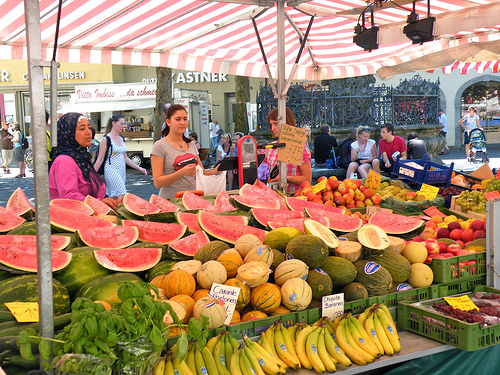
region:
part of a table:
[433, 345, 438, 353]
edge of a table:
[386, 337, 400, 354]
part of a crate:
[432, 305, 441, 320]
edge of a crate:
[426, 323, 431, 333]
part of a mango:
[323, 290, 330, 301]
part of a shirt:
[182, 180, 189, 190]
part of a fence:
[366, 104, 378, 124]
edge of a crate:
[420, 292, 431, 337]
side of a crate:
[435, 311, 442, 323]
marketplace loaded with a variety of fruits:
[1, 1, 498, 374]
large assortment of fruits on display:
[1, 159, 498, 374]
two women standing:
[46, 102, 228, 197]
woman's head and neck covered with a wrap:
[56, 113, 97, 154]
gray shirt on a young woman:
[149, 134, 202, 201]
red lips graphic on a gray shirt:
[170, 151, 201, 172]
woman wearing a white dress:
[95, 111, 147, 195]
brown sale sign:
[274, 123, 313, 166]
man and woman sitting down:
[343, 122, 410, 175]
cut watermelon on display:
[93, 244, 164, 275]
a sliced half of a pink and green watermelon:
[93, 245, 158, 271]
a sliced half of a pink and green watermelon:
[2, 244, 72, 271]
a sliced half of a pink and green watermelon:
[1, 230, 68, 252]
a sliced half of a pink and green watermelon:
[169, 230, 209, 255]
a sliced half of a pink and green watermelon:
[368, 209, 419, 237]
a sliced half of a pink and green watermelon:
[306, 205, 361, 234]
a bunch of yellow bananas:
[335, 310, 375, 362]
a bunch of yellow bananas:
[362, 303, 399, 353]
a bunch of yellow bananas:
[297, 321, 344, 371]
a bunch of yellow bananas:
[232, 340, 263, 373]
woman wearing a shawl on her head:
[46, 109, 107, 202]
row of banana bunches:
[141, 300, 403, 373]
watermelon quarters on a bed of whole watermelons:
[1, 177, 426, 316]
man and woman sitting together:
[345, 122, 407, 178]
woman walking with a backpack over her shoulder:
[91, 111, 148, 198]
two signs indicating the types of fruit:
[208, 279, 346, 326]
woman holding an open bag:
[148, 101, 226, 201]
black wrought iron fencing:
[254, 71, 444, 133]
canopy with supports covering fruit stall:
[1, 0, 498, 337]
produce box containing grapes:
[450, 177, 499, 222]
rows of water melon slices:
[2, 185, 430, 272]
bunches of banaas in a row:
[157, 301, 399, 373]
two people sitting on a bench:
[337, 119, 418, 179]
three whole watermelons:
[7, 242, 142, 322]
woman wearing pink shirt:
[43, 112, 108, 206]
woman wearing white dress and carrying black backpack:
[86, 115, 135, 192]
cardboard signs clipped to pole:
[272, 118, 307, 170]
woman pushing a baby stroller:
[457, 105, 496, 160]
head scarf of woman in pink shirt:
[44, 112, 101, 175]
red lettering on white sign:
[74, 85, 156, 100]